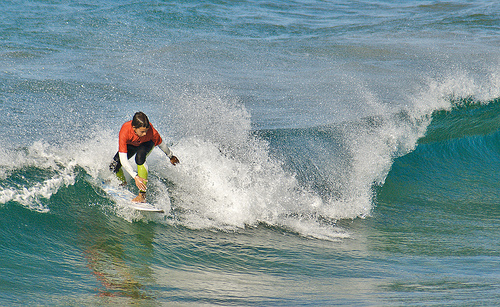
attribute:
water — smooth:
[169, 253, 362, 303]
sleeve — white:
[156, 140, 174, 161]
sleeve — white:
[120, 152, 138, 182]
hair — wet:
[127, 108, 152, 128]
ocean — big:
[0, 0, 498, 304]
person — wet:
[109, 110, 179, 204]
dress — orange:
[110, 110, 162, 168]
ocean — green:
[60, 221, 436, 303]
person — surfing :
[97, 100, 183, 249]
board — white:
[106, 177, 174, 229]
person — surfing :
[106, 89, 179, 219]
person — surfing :
[95, 100, 177, 233]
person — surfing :
[100, 106, 179, 224]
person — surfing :
[104, 107, 184, 215]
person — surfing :
[109, 93, 182, 223]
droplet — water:
[193, 107, 235, 139]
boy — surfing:
[108, 112, 179, 202]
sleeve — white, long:
[119, 151, 139, 177]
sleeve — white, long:
[157, 142, 174, 161]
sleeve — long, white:
[157, 144, 173, 160]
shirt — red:
[115, 119, 161, 152]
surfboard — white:
[109, 182, 167, 212]